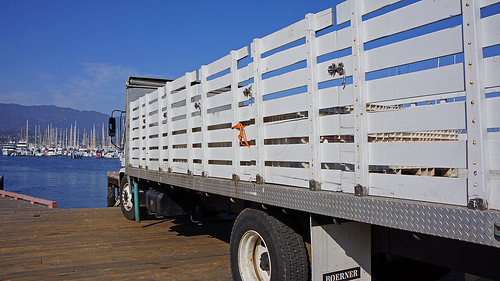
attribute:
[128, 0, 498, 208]
dock — large, wooden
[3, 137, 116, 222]
dock — filled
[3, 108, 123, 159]
masts — white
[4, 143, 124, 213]
water — blue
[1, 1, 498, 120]
sky — blue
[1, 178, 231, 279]
dock — wood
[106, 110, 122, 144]
mirror — side view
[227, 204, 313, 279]
tire — back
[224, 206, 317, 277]
wheel — black